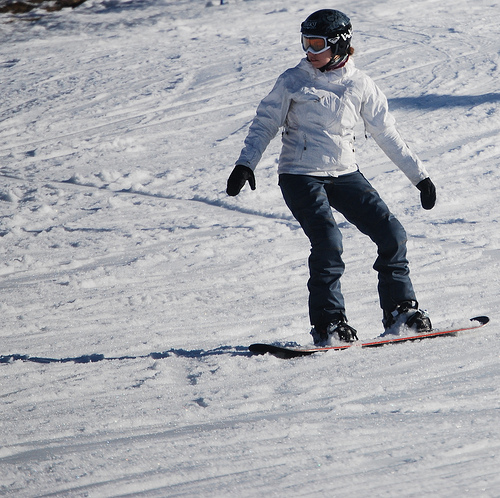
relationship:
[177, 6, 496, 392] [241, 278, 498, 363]
person on snowboard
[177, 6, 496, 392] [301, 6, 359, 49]
person wearing helmet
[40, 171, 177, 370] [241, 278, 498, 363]
snow on snowboard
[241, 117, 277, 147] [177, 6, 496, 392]
elbow of person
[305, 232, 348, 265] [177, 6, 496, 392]
knee of person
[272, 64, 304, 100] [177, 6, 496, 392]
shoulder of person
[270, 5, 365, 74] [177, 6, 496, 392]
head of person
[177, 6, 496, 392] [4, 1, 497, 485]
person in mountains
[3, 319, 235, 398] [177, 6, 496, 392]
shadow of person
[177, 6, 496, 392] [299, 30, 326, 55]
person wearing goggles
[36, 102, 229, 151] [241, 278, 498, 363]
tracks from snowboard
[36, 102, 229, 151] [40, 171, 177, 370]
tracks in snow